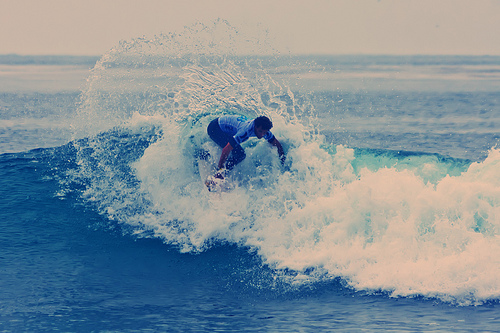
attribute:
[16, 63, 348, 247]
water — ocean splashing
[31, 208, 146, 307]
water — pristine, blue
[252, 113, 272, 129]
hair — black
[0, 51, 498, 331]
water — splashing, ocean splashing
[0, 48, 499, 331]
ocean — pristine blue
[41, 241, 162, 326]
water — ocean splashing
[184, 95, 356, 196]
surfer — leaning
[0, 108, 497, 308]
wave — crashing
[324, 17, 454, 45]
sky — clear, blue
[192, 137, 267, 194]
surfboard — white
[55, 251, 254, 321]
ocean — splashing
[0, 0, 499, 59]
sky — white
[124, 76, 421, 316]
water — splashing, ocean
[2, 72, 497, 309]
wave — crashing